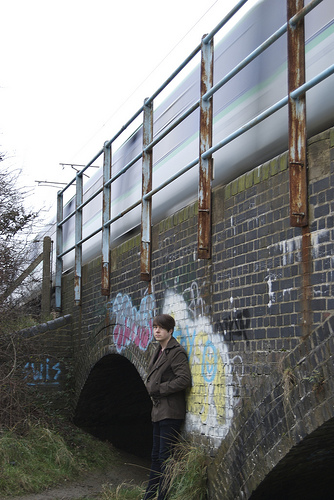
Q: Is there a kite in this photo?
A: No, there are no kites.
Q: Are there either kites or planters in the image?
A: No, there are no kites or planters.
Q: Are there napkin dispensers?
A: No, there are no napkin dispensers.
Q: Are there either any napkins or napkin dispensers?
A: No, there are no napkin dispensers or napkins.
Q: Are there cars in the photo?
A: No, there are no cars.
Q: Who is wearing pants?
A: The boy is wearing pants.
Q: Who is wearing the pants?
A: The boy is wearing pants.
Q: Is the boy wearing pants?
A: Yes, the boy is wearing pants.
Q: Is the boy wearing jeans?
A: No, the boy is wearing pants.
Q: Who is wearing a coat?
A: The boy is wearing a coat.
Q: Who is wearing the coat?
A: The boy is wearing a coat.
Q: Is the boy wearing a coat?
A: Yes, the boy is wearing a coat.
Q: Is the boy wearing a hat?
A: No, the boy is wearing a coat.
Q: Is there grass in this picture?
A: Yes, there is grass.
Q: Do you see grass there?
A: Yes, there is grass.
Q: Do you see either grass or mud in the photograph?
A: Yes, there is grass.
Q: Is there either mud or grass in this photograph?
A: Yes, there is grass.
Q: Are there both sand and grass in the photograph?
A: No, there is grass but no sand.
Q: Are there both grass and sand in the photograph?
A: No, there is grass but no sand.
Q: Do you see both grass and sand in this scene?
A: No, there is grass but no sand.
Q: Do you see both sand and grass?
A: No, there is grass but no sand.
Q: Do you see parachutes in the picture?
A: No, there are no parachutes.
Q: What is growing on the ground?
A: The grass is growing on the ground.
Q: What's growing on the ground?
A: The grass is growing on the ground.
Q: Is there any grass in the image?
A: Yes, there is grass.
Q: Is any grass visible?
A: Yes, there is grass.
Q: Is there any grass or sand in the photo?
A: Yes, there is grass.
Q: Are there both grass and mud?
A: No, there is grass but no mud.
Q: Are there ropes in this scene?
A: No, there are no ropes.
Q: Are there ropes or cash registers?
A: No, there are no ropes or cash registers.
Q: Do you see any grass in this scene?
A: Yes, there is grass.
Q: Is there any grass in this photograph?
A: Yes, there is grass.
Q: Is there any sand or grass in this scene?
A: Yes, there is grass.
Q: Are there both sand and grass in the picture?
A: No, there is grass but no sand.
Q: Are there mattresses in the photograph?
A: No, there are no mattresses.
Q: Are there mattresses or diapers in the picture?
A: No, there are no mattresses or diapers.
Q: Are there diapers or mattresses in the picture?
A: No, there are no mattresses or diapers.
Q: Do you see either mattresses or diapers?
A: No, there are no mattresses or diapers.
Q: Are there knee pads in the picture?
A: No, there are no knee pads.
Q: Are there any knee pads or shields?
A: No, there are no knee pads or shields.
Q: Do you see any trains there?
A: Yes, there is a train.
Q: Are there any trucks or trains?
A: Yes, there is a train.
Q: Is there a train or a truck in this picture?
A: Yes, there is a train.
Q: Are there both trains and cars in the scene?
A: No, there is a train but no cars.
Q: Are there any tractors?
A: No, there are no tractors.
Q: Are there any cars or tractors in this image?
A: No, there are no tractors or cars.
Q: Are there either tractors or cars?
A: No, there are no tractors or cars.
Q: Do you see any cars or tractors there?
A: No, there are no tractors or cars.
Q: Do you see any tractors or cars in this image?
A: No, there are no tractors or cars.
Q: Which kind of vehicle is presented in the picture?
A: The vehicle is a train.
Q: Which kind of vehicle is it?
A: The vehicle is a train.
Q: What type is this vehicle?
A: This is a train.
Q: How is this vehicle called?
A: This is a train.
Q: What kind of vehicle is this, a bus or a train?
A: This is a train.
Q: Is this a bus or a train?
A: This is a train.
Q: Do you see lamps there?
A: No, there are no lamps.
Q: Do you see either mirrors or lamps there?
A: No, there are no lamps or mirrors.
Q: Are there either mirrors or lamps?
A: No, there are no lamps or mirrors.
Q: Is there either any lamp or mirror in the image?
A: No, there are no lamps or mirrors.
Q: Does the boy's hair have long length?
A: Yes, the hair is long.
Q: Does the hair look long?
A: Yes, the hair is long.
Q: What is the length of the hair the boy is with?
A: The hair is long.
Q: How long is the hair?
A: The hair is long.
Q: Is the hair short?
A: No, the hair is long.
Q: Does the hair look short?
A: No, the hair is long.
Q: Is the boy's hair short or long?
A: The hair is long.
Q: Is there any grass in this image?
A: Yes, there is grass.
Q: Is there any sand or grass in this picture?
A: Yes, there is grass.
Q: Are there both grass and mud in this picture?
A: No, there is grass but no mud.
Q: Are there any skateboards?
A: No, there are no skateboards.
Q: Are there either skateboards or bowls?
A: No, there are no skateboards or bowls.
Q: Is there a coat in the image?
A: Yes, there is a coat.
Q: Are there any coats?
A: Yes, there is a coat.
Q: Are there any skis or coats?
A: Yes, there is a coat.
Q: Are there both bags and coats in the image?
A: No, there is a coat but no bags.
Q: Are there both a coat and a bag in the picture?
A: No, there is a coat but no bags.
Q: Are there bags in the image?
A: No, there are no bags.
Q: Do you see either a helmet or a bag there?
A: No, there are no bags or helmets.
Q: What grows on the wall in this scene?
A: The weeds grow on the wall.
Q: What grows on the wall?
A: The weeds grow on the wall.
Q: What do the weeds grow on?
A: The weeds grow on the wall.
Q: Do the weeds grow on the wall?
A: Yes, the weeds grow on the wall.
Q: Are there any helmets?
A: No, there are no helmets.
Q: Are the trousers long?
A: Yes, the trousers are long.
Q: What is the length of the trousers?
A: The trousers are long.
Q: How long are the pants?
A: The pants are long.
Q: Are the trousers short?
A: No, the trousers are long.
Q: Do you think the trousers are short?
A: No, the trousers are long.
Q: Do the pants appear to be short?
A: No, the pants are long.